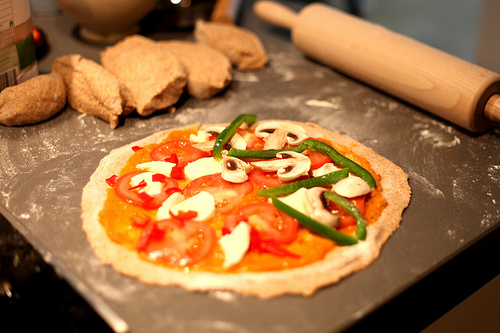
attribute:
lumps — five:
[4, 19, 274, 131]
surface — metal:
[4, 42, 499, 328]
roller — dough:
[233, 1, 499, 150]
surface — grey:
[0, 16, 499, 325]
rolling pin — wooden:
[252, 2, 500, 135]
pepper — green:
[212, 115, 376, 253]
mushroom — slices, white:
[127, 121, 374, 264]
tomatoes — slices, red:
[107, 119, 387, 281]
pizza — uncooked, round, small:
[80, 111, 414, 296]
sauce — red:
[98, 119, 380, 268]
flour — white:
[14, 117, 107, 152]